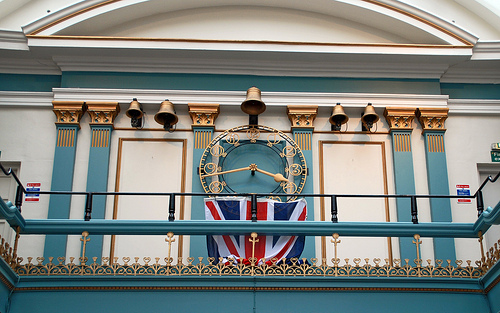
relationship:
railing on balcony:
[19, 205, 491, 249] [14, 249, 497, 311]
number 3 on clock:
[283, 160, 309, 178] [199, 124, 307, 200]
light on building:
[126, 100, 144, 119] [1, 0, 499, 310]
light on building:
[151, 97, 180, 128] [1, 0, 499, 310]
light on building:
[241, 85, 267, 116] [1, 0, 499, 310]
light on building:
[328, 102, 349, 126] [1, 0, 499, 310]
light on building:
[358, 100, 380, 126] [1, 0, 499, 310]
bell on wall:
[125, 98, 144, 120] [46, 57, 476, 308]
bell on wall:
[151, 99, 178, 131] [46, 57, 476, 308]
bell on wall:
[240, 86, 266, 116] [46, 57, 476, 308]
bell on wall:
[328, 104, 349, 126] [46, 57, 476, 308]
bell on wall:
[359, 101, 378, 128] [46, 57, 476, 308]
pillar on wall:
[38, 120, 77, 262] [1, 70, 499, 310]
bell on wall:
[240, 86, 266, 116] [1, 72, 498, 276]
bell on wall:
[328, 104, 349, 126] [125, 51, 495, 266]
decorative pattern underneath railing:
[1, 227, 498, 278] [1, 153, 499, 221]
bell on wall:
[328, 104, 349, 126] [1, 72, 498, 276]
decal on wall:
[115, 137, 189, 257] [56, 85, 443, 242]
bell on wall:
[122, 96, 147, 125] [1, 72, 498, 276]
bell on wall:
[328, 104, 349, 126] [3, 41, 498, 285]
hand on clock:
[191, 161, 252, 182] [199, 124, 307, 200]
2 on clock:
[281, 144, 295, 158] [199, 124, 307, 200]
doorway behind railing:
[2, 159, 20, 249] [0, 167, 498, 254]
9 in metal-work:
[213, 141, 231, 159] [198, 153, 223, 173]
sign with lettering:
[464, 136, 496, 163] [464, 134, 484, 172]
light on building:
[328, 102, 359, 134] [1, 0, 499, 310]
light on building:
[362, 102, 378, 126] [1, 0, 499, 310]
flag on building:
[196, 189, 313, 274] [1, 0, 499, 310]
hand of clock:
[202, 163, 249, 177] [199, 118, 311, 200]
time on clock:
[205, 153, 295, 188] [199, 124, 307, 200]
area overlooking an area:
[0, 242, 491, 310] [0, 242, 491, 310]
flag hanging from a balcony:
[204, 196, 307, 267] [0, 157, 497, 311]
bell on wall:
[125, 98, 144, 120] [1, 72, 498, 276]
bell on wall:
[154, 99, 179, 126] [1, 72, 498, 276]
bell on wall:
[323, 100, 350, 129] [1, 72, 498, 276]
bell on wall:
[359, 101, 378, 125] [1, 72, 498, 276]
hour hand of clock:
[243, 160, 294, 188] [191, 127, 307, 206]